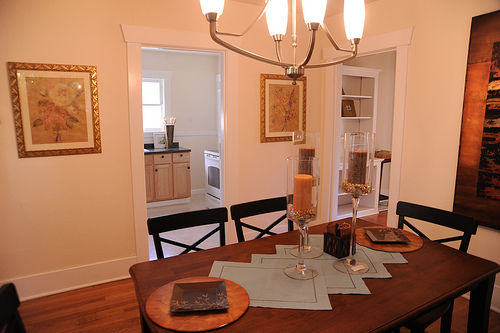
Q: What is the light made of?
A: Glass and metal.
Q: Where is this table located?
A: The dining room.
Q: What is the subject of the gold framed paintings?
A: Flowers.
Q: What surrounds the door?
A: A white, wooden frame.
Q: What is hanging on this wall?
A: A painting in a gold frame.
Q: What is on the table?
A: A grey place mat.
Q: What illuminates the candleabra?
A: Four lamps with bulbs.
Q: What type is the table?
A: A brown dining table.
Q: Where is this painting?
A: It is hanging on the wall.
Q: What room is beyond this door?
A: A kitchen.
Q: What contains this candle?
A: A glass, cylindrical candle holder.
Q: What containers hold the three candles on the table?
A: Clear candle holders.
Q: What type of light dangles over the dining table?
A: Chandelier lamp.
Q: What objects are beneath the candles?
A: Place mats.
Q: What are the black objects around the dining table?
A: Chairs.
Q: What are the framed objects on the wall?
A: Art.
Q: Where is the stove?
A: In the kitchen next to the dining room.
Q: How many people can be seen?
A: None.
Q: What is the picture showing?
A: A dining room.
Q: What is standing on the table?
A: Candles.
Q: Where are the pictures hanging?
A: On the wall.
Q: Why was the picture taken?
A: To capture the rooms.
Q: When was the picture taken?
A: During the day.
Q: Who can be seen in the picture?
A: No one.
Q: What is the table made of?
A: Wood.